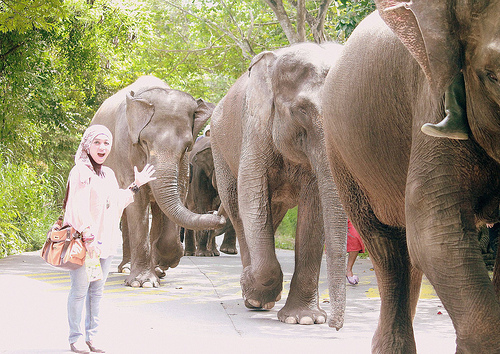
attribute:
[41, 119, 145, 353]
woman — excited, suprised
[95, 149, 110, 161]
mouth — open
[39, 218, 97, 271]
purse — brown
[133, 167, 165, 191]
hand — here, open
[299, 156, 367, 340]
trunk — long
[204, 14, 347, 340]
elephant — grey, walking, small, here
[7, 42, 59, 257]
plant — green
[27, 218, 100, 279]
bag — brown, held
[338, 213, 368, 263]
shorts — red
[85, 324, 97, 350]
boot — black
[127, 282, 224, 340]
path — concrete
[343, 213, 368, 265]
cloth — red